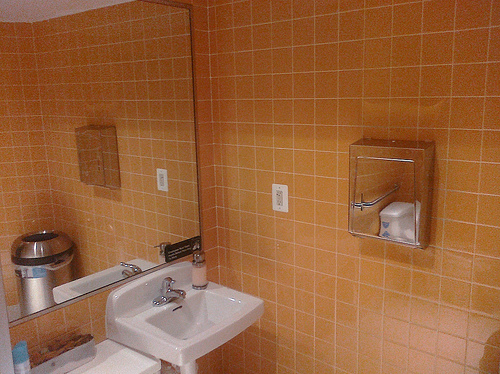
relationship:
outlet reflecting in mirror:
[156, 168, 170, 193] [3, 2, 205, 326]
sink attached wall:
[106, 260, 266, 372] [1, 0, 228, 372]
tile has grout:
[282, 258, 464, 368] [302, 270, 439, 361]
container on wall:
[334, 127, 438, 259] [210, 5, 459, 125]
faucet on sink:
[152, 274, 185, 306] [110, 258, 270, 361]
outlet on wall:
[270, 183, 289, 213] [189, 1, 498, 372]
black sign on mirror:
[163, 234, 200, 262] [4, 5, 214, 305]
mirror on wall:
[3, 2, 205, 326] [196, 23, 440, 370]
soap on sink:
[187, 245, 212, 292] [110, 258, 270, 361]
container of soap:
[188, 247, 215, 286] [187, 249, 209, 298]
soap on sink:
[190, 250, 208, 291] [87, 246, 273, 367]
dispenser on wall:
[347, 138, 432, 246] [213, 18, 498, 139]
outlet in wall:
[270, 183, 289, 213] [313, 92, 345, 115]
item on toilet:
[7, 338, 41, 374] [15, 329, 167, 374]